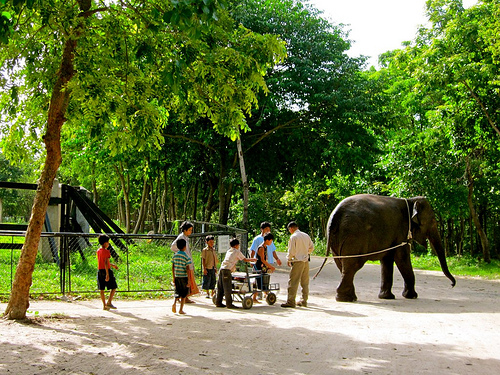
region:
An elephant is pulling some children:
[72, 130, 473, 341]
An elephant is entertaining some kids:
[80, 165, 465, 361]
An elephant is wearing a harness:
[71, 155, 482, 365]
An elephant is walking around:
[75, 132, 483, 354]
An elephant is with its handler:
[62, 155, 478, 355]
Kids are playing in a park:
[80, 162, 478, 363]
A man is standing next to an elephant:
[280, 172, 460, 323]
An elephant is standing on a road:
[312, 156, 459, 331]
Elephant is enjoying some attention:
[60, 173, 466, 315]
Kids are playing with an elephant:
[86, 173, 471, 331]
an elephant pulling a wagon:
[323, 185, 458, 305]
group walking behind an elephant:
[91, 216, 319, 320]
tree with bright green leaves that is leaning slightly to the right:
[11, 49, 273, 327]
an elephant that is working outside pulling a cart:
[220, 189, 457, 309]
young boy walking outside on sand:
[91, 232, 128, 319]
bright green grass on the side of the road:
[462, 260, 496, 279]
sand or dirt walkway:
[340, 322, 449, 362]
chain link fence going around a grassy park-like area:
[130, 243, 167, 288]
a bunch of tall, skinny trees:
[105, 145, 215, 225]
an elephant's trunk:
[430, 229, 461, 289]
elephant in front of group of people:
[313, 188, 464, 305]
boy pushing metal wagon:
[221, 235, 280, 312]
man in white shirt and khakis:
[279, 212, 317, 316]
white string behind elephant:
[314, 227, 411, 262]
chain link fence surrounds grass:
[0, 210, 244, 303]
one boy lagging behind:
[89, 230, 126, 315]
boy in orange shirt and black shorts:
[93, 234, 127, 312]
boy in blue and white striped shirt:
[171, 239, 196, 311]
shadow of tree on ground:
[2, 293, 498, 374]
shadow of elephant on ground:
[361, 280, 499, 320]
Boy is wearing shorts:
[92, 232, 121, 312]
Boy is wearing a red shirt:
[94, 242, 116, 274]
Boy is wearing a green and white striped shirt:
[170, 247, 191, 279]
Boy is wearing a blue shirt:
[248, 234, 278, 266]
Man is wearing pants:
[281, 255, 309, 306]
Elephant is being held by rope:
[301, 188, 459, 299]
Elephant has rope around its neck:
[393, 188, 418, 251]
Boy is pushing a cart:
[212, 235, 280, 307]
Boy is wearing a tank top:
[252, 242, 272, 269]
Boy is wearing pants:
[214, 265, 235, 307]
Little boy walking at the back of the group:
[92, 231, 123, 313]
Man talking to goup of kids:
[279, 216, 317, 311]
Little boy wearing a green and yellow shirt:
[170, 235, 197, 313]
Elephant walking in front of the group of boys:
[312, 191, 455, 304]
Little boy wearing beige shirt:
[212, 236, 257, 312]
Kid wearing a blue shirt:
[249, 220, 281, 272]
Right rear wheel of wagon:
[236, 292, 255, 312]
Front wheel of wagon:
[254, 289, 282, 307]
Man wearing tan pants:
[286, 257, 311, 299]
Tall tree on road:
[0, 0, 349, 368]